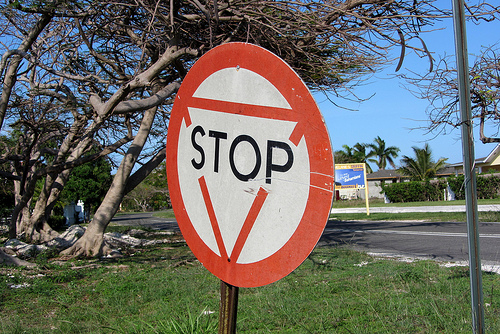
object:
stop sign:
[163, 40, 335, 289]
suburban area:
[0, 118, 499, 276]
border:
[162, 39, 336, 288]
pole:
[451, 0, 486, 332]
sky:
[0, 1, 499, 176]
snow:
[3, 280, 33, 290]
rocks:
[10, 241, 37, 259]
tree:
[0, 0, 499, 243]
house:
[363, 164, 457, 200]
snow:
[200, 308, 217, 315]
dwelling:
[450, 143, 499, 184]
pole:
[353, 183, 359, 199]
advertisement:
[333, 162, 369, 192]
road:
[106, 213, 498, 263]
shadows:
[296, 222, 448, 274]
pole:
[212, 279, 239, 333]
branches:
[363, 19, 434, 54]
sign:
[331, 163, 368, 190]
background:
[0, 0, 499, 333]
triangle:
[174, 94, 308, 265]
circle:
[162, 40, 335, 291]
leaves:
[420, 159, 430, 168]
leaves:
[366, 154, 372, 158]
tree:
[360, 136, 399, 173]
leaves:
[372, 148, 378, 155]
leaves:
[70, 173, 80, 178]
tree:
[3, 118, 115, 229]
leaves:
[422, 152, 430, 160]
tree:
[397, 140, 448, 185]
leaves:
[1, 172, 11, 183]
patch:
[480, 299, 494, 309]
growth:
[0, 241, 499, 333]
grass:
[0, 219, 499, 333]